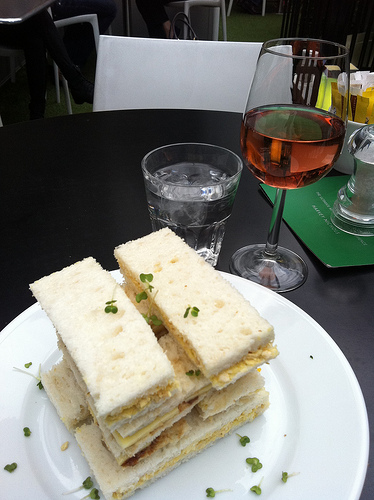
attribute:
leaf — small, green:
[203, 483, 214, 494]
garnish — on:
[180, 301, 202, 318]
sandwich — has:
[23, 252, 188, 433]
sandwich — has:
[110, 221, 283, 393]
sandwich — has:
[36, 355, 274, 498]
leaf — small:
[100, 273, 161, 316]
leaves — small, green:
[104, 270, 205, 328]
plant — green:
[4, 460, 21, 473]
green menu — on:
[260, 173, 373, 273]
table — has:
[3, 104, 371, 498]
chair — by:
[87, 33, 306, 117]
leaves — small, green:
[234, 433, 266, 470]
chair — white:
[91, 35, 300, 113]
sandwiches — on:
[25, 224, 280, 498]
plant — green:
[201, 484, 236, 498]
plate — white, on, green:
[2, 266, 373, 496]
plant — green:
[236, 432, 252, 448]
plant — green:
[243, 454, 262, 471]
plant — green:
[249, 480, 264, 493]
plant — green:
[203, 485, 216, 498]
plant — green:
[280, 471, 289, 481]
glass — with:
[135, 137, 244, 280]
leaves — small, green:
[181, 304, 198, 318]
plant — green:
[73, 476, 101, 498]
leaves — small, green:
[137, 266, 157, 303]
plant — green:
[241, 452, 266, 473]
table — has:
[0, 204, 363, 498]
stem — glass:
[264, 180, 289, 261]